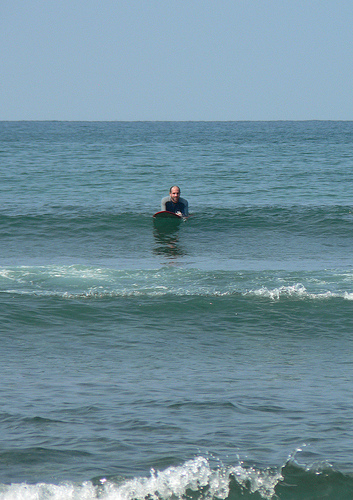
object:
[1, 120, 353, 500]
water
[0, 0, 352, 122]
sky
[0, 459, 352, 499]
wave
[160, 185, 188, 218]
guy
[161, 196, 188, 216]
wet suit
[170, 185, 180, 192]
hairline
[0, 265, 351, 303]
wave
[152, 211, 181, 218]
board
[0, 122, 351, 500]
ocean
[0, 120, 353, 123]
coastline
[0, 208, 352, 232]
ripples